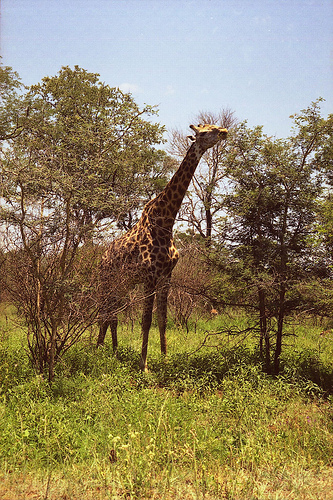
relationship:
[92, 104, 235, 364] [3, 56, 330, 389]
giraffe among trees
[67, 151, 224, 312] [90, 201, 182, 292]
spots on body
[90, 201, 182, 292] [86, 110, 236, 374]
body of giraffe's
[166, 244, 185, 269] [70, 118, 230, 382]
bump on giraffe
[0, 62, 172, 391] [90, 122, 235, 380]
tree in front of giraffe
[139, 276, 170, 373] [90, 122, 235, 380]
legs of giraffe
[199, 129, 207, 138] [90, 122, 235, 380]
eye of giraffe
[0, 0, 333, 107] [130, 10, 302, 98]
clouds in sky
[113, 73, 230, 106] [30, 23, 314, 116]
clouds in sky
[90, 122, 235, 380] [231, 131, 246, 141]
giraffe eating leaves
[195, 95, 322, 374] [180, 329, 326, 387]
tree has shadow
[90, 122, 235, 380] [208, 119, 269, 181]
giraffe eating leaves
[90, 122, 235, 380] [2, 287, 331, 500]
giraffe standing on grass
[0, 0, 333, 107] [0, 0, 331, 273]
clouds in sky